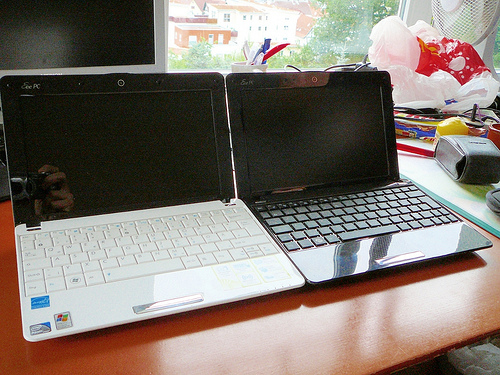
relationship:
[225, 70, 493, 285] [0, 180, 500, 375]
black laptop on desk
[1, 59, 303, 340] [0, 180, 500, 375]
laptop on desk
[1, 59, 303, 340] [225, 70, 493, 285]
laptop sitting next to black laptop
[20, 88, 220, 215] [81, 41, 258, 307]
screen of laptop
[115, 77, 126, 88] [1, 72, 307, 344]
webcam of laptop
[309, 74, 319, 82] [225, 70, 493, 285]
webcam of black laptop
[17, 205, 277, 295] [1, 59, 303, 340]
keyboard of laptop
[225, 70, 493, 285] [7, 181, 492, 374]
black laptop on desk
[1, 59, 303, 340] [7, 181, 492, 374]
laptop on desk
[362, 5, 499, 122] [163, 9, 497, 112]
bag by window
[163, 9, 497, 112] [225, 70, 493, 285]
window behind black laptop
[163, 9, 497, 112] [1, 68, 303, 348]
window behind computer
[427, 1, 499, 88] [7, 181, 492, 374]
white fan on desk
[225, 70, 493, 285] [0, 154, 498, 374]
black laptop on table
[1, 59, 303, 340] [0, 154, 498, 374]
laptop on table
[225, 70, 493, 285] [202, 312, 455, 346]
black laptop are on table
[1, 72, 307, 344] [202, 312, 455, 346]
laptop are on table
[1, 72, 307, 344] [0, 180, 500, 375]
laptop on desk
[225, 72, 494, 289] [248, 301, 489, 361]
black laptop on table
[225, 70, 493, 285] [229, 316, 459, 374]
black laptop on table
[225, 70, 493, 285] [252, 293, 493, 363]
black laptop on table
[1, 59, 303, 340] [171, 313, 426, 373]
laptop on table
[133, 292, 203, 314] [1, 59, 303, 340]
touchpad of laptop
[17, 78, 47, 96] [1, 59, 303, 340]
logo of laptop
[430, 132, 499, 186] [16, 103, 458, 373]
case on desk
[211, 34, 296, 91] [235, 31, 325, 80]
cup of pens